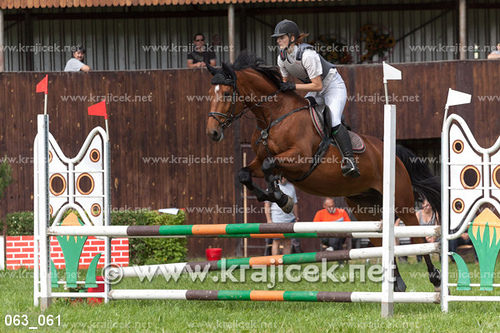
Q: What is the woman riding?
A: A horse.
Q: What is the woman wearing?
A: Black Helmet.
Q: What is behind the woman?
A: Wooden wall.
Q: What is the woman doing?
A: Jumping the horse.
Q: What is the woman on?
A: A horse.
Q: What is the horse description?
A: Black and Brown.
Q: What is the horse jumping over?
A: A Obstacle.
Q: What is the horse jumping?
A: Poles.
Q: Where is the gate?
A: In the grass.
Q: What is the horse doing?
A: Jumping an obstacle.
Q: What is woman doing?
A: Riding a horse.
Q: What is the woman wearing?
A: A white outfit.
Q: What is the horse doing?
A: Jumping.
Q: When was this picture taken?
A: Daytime.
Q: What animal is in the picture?
A: Horse.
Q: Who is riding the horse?
A: Jockey.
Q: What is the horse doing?
A: Jumping.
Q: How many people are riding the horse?
A: 1.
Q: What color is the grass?
A: Green.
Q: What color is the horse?
A: Brown.